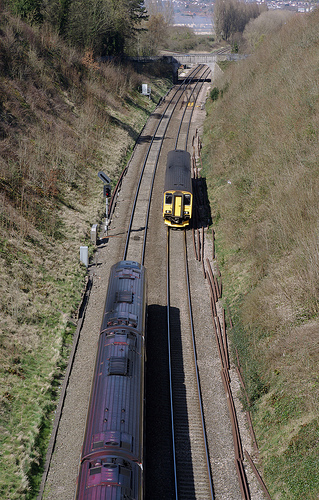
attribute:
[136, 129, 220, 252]
train — long, car, small, yellow, parallel, red, moving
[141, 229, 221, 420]
track — electronic, switch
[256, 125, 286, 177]
grass — brown, dead, covered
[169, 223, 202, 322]
tracks — metal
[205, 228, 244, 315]
log — strewn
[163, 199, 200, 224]
light — traffic, red, signal, train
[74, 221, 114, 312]
area — hollowed out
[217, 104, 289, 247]
vegetation — dry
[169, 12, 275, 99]
bridge — crosses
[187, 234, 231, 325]
rod — small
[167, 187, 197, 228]
door — yellow